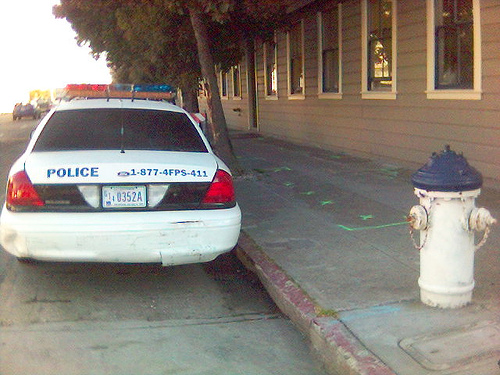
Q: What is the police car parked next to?
A: Fire hydrant.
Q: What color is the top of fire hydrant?
A: Blue.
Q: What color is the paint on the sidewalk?
A: Green.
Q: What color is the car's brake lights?
A: Red.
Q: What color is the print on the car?
A: Blue.